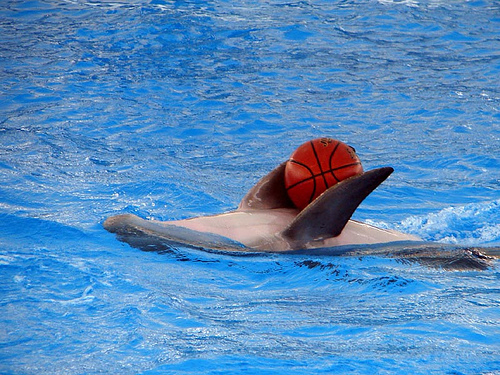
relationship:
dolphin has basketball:
[101, 157, 499, 290] [283, 137, 362, 211]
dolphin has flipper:
[101, 157, 499, 290] [274, 165, 394, 239]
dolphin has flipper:
[101, 157, 499, 290] [239, 159, 302, 210]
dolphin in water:
[101, 157, 499, 290] [1, 1, 499, 372]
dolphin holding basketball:
[101, 157, 499, 290] [283, 137, 362, 211]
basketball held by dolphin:
[283, 137, 362, 211] [101, 157, 499, 290]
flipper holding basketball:
[274, 165, 394, 239] [283, 137, 362, 211]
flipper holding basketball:
[239, 159, 302, 210] [283, 137, 362, 211]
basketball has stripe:
[283, 137, 362, 211] [283, 160, 362, 191]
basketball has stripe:
[283, 137, 362, 211] [308, 137, 330, 191]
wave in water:
[365, 196, 499, 236] [1, 1, 499, 372]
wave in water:
[432, 221, 498, 248] [1, 1, 499, 372]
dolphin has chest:
[101, 157, 499, 290] [159, 208, 299, 253]